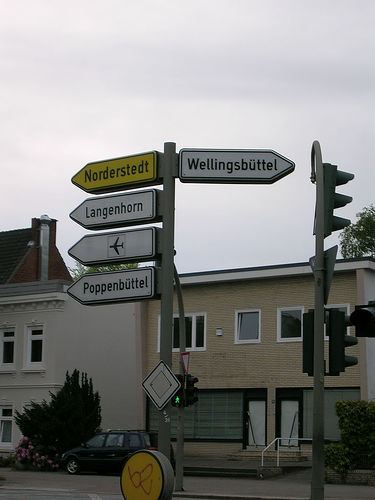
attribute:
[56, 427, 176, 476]
car —  black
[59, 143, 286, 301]
signs — White 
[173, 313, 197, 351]
window — Small , white 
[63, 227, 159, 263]
sign — white , black 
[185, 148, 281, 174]
sign — triangle shaped, white , red 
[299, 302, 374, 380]
traffic signals — black 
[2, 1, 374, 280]
sky — blue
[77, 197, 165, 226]
street sign — black , white 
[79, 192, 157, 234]
sign — White 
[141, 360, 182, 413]
sign —  triangular,  white , white , diamond shaped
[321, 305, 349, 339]
window — white , Small 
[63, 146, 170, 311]
four signs —  four 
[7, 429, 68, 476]
purple flowers —  purple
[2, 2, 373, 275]
clouds — white 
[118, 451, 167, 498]
sign — round , yellow 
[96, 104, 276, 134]
clouds — white 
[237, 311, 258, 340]
window —   building's,  white, Small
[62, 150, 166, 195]
sign — yellow